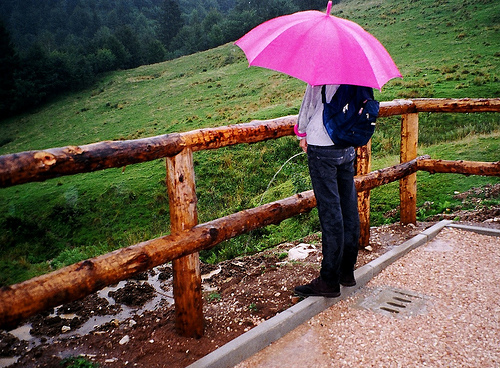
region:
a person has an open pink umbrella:
[228, 5, 399, 329]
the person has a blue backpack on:
[295, 85, 397, 178]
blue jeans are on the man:
[305, 139, 364, 278]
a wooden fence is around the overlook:
[3, 98, 498, 366]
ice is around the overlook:
[7, 260, 199, 362]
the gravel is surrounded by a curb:
[261, 223, 499, 363]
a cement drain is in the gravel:
[368, 284, 424, 324]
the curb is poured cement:
[238, 270, 373, 349]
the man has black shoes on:
[289, 265, 359, 300]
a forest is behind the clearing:
[8, 3, 494, 305]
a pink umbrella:
[234, 3, 404, 90]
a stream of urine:
[242, 148, 307, 251]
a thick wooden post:
[168, 135, 200, 336]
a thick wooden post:
[400, 113, 417, 222]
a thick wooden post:
[3, 99, 407, 186]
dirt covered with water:
[4, 264, 171, 366]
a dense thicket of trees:
[0, 1, 309, 105]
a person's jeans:
[307, 148, 358, 290]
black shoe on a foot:
[293, 280, 338, 297]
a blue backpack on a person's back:
[318, 79, 380, 145]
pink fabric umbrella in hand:
[236, 1, 405, 93]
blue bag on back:
[321, 84, 381, 150]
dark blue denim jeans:
[311, 144, 363, 269]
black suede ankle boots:
[291, 248, 358, 298]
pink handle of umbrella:
[292, 120, 307, 137]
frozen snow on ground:
[3, 264, 198, 334]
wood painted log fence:
[398, 94, 497, 221]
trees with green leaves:
[3, 0, 336, 120]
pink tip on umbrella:
[322, 1, 333, 18]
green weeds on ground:
[9, 193, 153, 278]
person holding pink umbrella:
[228, 0, 406, 300]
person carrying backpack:
[296, 78, 380, 293]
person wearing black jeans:
[298, 79, 383, 296]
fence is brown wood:
[0, 97, 495, 339]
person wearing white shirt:
[296, 81, 377, 303]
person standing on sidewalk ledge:
[295, 82, 373, 297]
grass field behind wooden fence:
[3, 4, 497, 271]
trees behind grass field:
[3, 1, 327, 128]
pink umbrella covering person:
[232, 1, 402, 303]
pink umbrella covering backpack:
[230, 1, 402, 159]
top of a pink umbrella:
[235, 3, 404, 88]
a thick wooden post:
[400, 99, 417, 228]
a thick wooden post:
[165, 139, 202, 340]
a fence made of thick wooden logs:
[0, 98, 498, 325]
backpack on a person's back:
[322, 81, 379, 146]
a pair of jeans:
[303, 146, 363, 287]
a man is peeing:
[250, 148, 312, 208]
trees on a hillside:
[2, 1, 298, 109]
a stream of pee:
[253, 149, 309, 204]